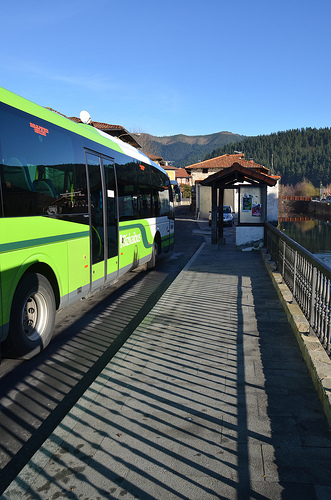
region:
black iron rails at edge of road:
[263, 221, 330, 354]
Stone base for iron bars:
[259, 244, 329, 420]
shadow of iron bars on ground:
[0, 257, 282, 498]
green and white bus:
[0, 83, 179, 368]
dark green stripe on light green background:
[2, 214, 174, 254]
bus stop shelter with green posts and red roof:
[201, 161, 275, 250]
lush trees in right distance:
[207, 126, 329, 220]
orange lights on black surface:
[25, 117, 159, 175]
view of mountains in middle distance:
[86, 126, 246, 169]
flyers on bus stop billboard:
[239, 191, 264, 220]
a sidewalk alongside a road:
[2, 245, 322, 498]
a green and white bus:
[4, 92, 178, 313]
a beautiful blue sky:
[0, 1, 329, 137]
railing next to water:
[257, 212, 330, 356]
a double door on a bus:
[77, 142, 126, 288]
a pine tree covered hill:
[205, 127, 329, 174]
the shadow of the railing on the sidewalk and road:
[3, 249, 326, 496]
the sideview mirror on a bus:
[172, 178, 183, 208]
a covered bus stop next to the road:
[202, 163, 275, 251]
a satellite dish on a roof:
[76, 106, 96, 129]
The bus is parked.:
[20, 96, 176, 269]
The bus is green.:
[47, 113, 180, 257]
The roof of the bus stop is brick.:
[195, 161, 277, 187]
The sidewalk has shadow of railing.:
[154, 247, 249, 466]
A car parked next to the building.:
[201, 195, 246, 231]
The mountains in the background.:
[136, 122, 265, 172]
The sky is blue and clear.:
[83, 18, 276, 113]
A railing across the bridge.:
[261, 214, 328, 297]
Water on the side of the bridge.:
[300, 208, 326, 259]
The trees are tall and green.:
[260, 120, 319, 178]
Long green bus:
[0, 85, 196, 340]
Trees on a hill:
[223, 112, 329, 202]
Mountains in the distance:
[122, 96, 259, 172]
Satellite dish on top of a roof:
[76, 103, 93, 135]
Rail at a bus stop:
[266, 222, 329, 368]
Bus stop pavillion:
[175, 127, 278, 260]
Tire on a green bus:
[8, 265, 67, 355]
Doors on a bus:
[74, 130, 122, 325]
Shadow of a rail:
[56, 256, 250, 497]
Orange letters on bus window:
[18, 115, 52, 142]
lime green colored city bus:
[3, 82, 201, 377]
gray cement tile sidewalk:
[164, 300, 287, 495]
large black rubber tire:
[7, 264, 63, 370]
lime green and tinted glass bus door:
[81, 135, 124, 306]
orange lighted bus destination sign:
[26, 116, 56, 145]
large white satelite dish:
[71, 105, 93, 127]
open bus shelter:
[199, 158, 276, 255]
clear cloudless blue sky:
[41, 9, 327, 87]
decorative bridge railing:
[280, 225, 330, 358]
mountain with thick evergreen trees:
[277, 123, 329, 181]